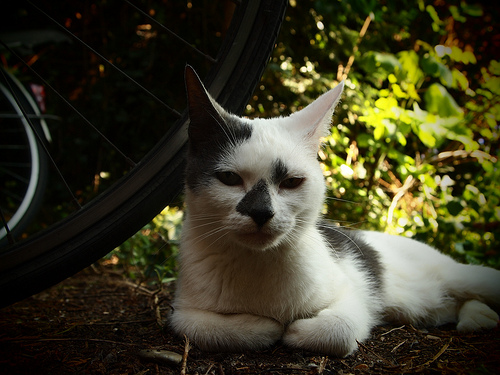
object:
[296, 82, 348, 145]
ear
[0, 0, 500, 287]
bush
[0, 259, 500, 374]
ground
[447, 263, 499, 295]
tail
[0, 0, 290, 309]
bicycle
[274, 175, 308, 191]
eyes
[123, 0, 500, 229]
tree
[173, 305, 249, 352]
leg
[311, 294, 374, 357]
leg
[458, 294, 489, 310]
leg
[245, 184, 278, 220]
nose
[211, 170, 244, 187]
right eye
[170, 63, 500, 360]
cat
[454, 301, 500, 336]
paw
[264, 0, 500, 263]
green trees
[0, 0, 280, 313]
wheel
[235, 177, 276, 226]
patch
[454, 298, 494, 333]
foot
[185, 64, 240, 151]
ear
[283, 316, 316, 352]
paw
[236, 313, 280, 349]
paw